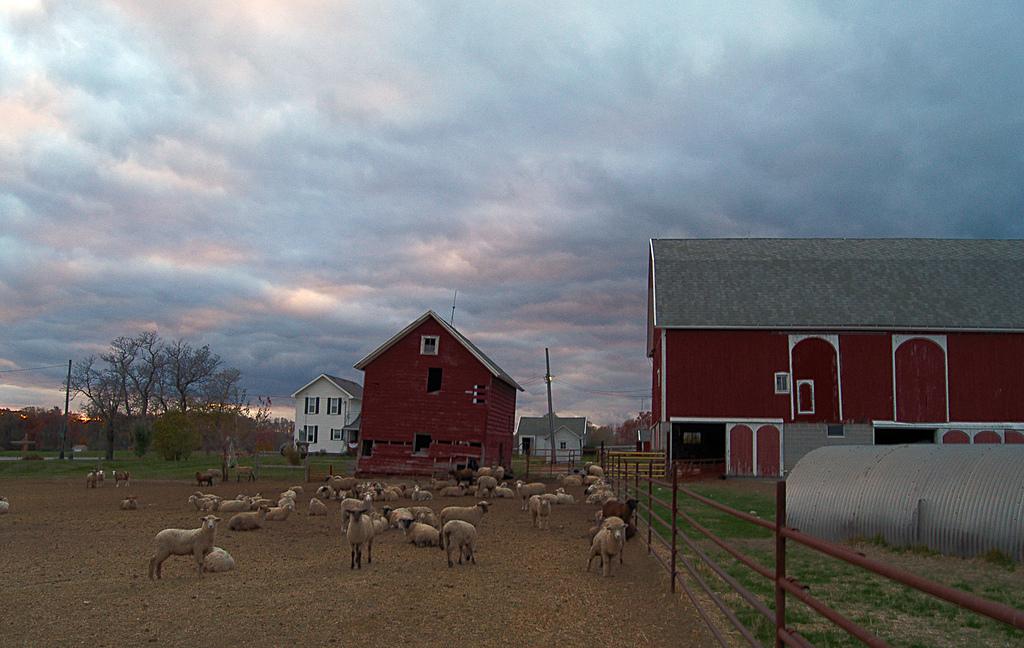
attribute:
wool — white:
[226, 495, 281, 543]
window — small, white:
[417, 332, 441, 361]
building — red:
[350, 306, 510, 475]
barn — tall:
[356, 314, 525, 483]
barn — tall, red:
[361, 317, 521, 467]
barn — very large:
[346, 308, 517, 481]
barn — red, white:
[356, 319, 512, 477]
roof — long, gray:
[646, 239, 1016, 345]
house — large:
[294, 375, 359, 469]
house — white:
[288, 377, 356, 458]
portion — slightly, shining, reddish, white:
[292, 293, 340, 320]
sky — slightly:
[11, 12, 610, 306]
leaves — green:
[197, 347, 217, 371]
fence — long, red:
[624, 446, 990, 643]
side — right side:
[220, 546, 583, 637]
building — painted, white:
[288, 377, 355, 460]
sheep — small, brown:
[605, 504, 638, 539]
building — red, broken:
[346, 310, 515, 499]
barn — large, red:
[639, 232, 1018, 462]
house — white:
[285, 375, 350, 451]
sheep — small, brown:
[141, 520, 234, 577]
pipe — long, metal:
[793, 530, 900, 589]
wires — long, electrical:
[9, 353, 102, 399]